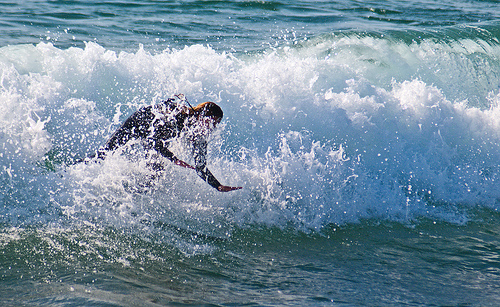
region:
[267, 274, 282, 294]
the sea water is clear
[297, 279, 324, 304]
the sea water is clear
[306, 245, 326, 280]
the sea water is clear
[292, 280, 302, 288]
the sea water is clear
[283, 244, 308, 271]
the sea water is clear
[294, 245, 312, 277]
the sea water is clear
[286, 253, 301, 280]
the sea water is clear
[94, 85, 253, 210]
a person in middle of a wave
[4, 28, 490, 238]
a wave crashing in the ocean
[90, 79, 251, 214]
woman surfing in the sea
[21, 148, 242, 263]
skateboard under a wave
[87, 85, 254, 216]
woman wears a black suit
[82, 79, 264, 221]
woman is turned to the right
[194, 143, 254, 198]
left arm of woman is extended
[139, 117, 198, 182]
right arm of woman is extended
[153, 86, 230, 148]
woman has brown hair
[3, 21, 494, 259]
a wave rolling in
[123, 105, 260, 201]
woman surfer falling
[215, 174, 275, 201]
a hand of the woman surfer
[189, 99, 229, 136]
the head of a surfer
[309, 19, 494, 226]
waves in the ocean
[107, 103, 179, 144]
back and body of a falling surfer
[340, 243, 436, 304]
calm water before the wave hits it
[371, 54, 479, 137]
white cap of a wave in the ocean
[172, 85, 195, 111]
sunglass string holding the glasses to the head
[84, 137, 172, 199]
Legs of a surfer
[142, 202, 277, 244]
surf board under the water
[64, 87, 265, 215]
person surfing a wave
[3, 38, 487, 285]
pretty big wave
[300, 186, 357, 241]
specks of water coming off the wave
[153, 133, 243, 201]
both hands oustretched in front of the body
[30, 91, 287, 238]
person leaning forward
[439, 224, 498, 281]
small ripples in the water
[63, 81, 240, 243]
person wearing a black wetsuit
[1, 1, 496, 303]
body of water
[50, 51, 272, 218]
person engulfed by the wave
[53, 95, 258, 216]
person in the water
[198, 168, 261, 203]
left hand of swimmer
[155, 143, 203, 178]
right hand of swimmer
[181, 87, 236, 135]
head of the swimmer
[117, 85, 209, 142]
body of the swimmer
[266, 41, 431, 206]
rippling waves in ocean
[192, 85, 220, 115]
hair of the swimmer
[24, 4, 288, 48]
waves in the background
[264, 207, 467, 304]
blue waves in ocean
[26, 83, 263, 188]
swimmer in the ocean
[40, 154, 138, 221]
splashing waves in ocean